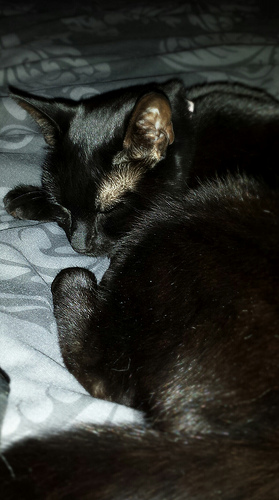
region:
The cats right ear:
[111, 98, 179, 156]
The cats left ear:
[9, 91, 59, 138]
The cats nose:
[70, 234, 92, 260]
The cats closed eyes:
[52, 197, 111, 213]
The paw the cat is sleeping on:
[5, 180, 53, 228]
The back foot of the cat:
[49, 263, 122, 412]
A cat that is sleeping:
[21, 91, 265, 486]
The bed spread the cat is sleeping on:
[1, 75, 267, 486]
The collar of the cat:
[165, 91, 197, 149]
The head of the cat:
[9, 89, 166, 246]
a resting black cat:
[2, 80, 277, 496]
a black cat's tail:
[1, 428, 272, 499]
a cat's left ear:
[118, 87, 175, 157]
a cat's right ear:
[6, 89, 74, 144]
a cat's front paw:
[3, 184, 58, 223]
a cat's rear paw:
[49, 266, 107, 395]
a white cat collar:
[184, 97, 194, 114]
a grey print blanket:
[3, 10, 278, 444]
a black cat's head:
[7, 84, 184, 265]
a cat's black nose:
[72, 245, 90, 254]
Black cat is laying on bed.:
[0, 77, 277, 495]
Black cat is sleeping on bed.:
[0, 77, 276, 497]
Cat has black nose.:
[73, 248, 86, 253]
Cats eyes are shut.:
[54, 197, 118, 215]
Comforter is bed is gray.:
[1, 0, 278, 93]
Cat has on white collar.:
[186, 99, 192, 118]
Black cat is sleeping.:
[0, 78, 277, 497]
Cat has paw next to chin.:
[2, 184, 55, 221]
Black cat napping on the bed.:
[0, 77, 277, 497]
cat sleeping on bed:
[11, 75, 272, 494]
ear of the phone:
[9, 92, 59, 140]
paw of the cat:
[0, 185, 69, 219]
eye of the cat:
[94, 191, 124, 219]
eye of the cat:
[51, 202, 76, 217]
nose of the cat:
[72, 242, 86, 249]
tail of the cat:
[47, 437, 133, 481]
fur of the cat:
[205, 132, 244, 196]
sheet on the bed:
[31, 353, 54, 398]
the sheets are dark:
[63, 0, 160, 55]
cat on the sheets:
[11, 258, 111, 342]